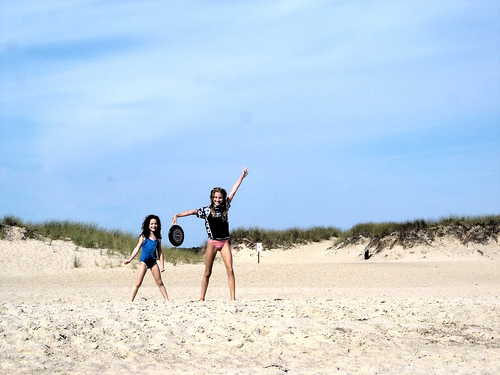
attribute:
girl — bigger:
[171, 167, 249, 302]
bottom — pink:
[205, 238, 230, 252]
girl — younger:
[104, 194, 176, 310]